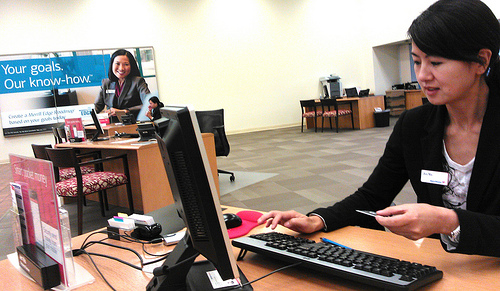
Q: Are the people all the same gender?
A: Yes, all the people are female.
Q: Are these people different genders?
A: No, all the people are female.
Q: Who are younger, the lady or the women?
A: The women are younger than the lady.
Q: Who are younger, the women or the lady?
A: The women are younger than the lady.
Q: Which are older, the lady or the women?
A: The lady are older than the women.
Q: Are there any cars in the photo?
A: No, there are no cars.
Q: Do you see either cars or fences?
A: No, there are no cars or fences.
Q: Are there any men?
A: No, there are no men.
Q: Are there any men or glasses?
A: No, there are no men or glasses.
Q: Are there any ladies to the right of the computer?
A: Yes, there is a lady to the right of the computer.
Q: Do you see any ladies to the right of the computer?
A: Yes, there is a lady to the right of the computer.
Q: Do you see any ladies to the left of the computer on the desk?
A: No, the lady is to the right of the computer.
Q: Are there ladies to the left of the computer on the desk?
A: No, the lady is to the right of the computer.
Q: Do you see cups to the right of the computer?
A: No, there is a lady to the right of the computer.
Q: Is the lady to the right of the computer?
A: Yes, the lady is to the right of the computer.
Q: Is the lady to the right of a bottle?
A: No, the lady is to the right of the computer.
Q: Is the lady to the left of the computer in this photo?
A: No, the lady is to the right of the computer.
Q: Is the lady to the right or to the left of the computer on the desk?
A: The lady is to the right of the computer.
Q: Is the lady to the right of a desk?
A: Yes, the lady is to the right of a desk.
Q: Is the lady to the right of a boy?
A: No, the lady is to the right of a desk.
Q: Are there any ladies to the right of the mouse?
A: Yes, there is a lady to the right of the mouse.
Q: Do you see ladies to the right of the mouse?
A: Yes, there is a lady to the right of the mouse.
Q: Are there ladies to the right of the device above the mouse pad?
A: Yes, there is a lady to the right of the mouse.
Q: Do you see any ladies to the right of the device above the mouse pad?
A: Yes, there is a lady to the right of the mouse.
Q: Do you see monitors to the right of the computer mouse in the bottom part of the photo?
A: No, there is a lady to the right of the computer mouse.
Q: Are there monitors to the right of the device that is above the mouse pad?
A: No, there is a lady to the right of the computer mouse.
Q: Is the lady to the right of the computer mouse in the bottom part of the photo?
A: Yes, the lady is to the right of the computer mouse.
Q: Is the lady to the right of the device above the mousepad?
A: Yes, the lady is to the right of the computer mouse.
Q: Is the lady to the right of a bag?
A: No, the lady is to the right of the computer mouse.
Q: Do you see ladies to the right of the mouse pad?
A: Yes, there is a lady to the right of the mouse pad.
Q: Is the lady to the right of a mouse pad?
A: Yes, the lady is to the right of a mouse pad.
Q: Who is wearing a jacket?
A: The lady is wearing a jacket.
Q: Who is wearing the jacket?
A: The lady is wearing a jacket.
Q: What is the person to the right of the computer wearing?
A: The lady is wearing a jacket.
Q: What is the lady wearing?
A: The lady is wearing a jacket.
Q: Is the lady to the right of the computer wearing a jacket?
A: Yes, the lady is wearing a jacket.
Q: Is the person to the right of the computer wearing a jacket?
A: Yes, the lady is wearing a jacket.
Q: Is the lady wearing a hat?
A: No, the lady is wearing a jacket.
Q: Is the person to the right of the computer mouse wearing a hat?
A: No, the lady is wearing a jacket.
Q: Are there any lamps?
A: No, there are no lamps.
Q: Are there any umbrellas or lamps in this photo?
A: No, there are no lamps or umbrellas.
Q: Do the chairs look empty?
A: Yes, the chairs are empty.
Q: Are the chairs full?
A: No, the chairs are empty.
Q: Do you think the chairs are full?
A: No, the chairs are empty.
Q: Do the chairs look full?
A: No, the chairs are empty.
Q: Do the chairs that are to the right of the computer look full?
A: No, the chairs are empty.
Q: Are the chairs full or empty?
A: The chairs are empty.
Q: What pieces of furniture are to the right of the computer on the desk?
A: The pieces of furniture are chairs.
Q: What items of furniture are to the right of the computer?
A: The pieces of furniture are chairs.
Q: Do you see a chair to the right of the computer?
A: Yes, there are chairs to the right of the computer.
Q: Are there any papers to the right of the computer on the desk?
A: No, there are chairs to the right of the computer.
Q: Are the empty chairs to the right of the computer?
A: Yes, the chairs are to the right of the computer.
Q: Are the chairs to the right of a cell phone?
A: No, the chairs are to the right of the computer.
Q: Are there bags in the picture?
A: No, there are no bags.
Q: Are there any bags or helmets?
A: No, there are no bags or helmets.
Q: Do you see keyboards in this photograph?
A: Yes, there is a keyboard.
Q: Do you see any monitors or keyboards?
A: Yes, there is a keyboard.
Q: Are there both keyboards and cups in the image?
A: No, there is a keyboard but no cups.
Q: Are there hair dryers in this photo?
A: No, there are no hair dryers.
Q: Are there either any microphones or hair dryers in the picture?
A: No, there are no hair dryers or microphones.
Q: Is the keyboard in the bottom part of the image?
A: Yes, the keyboard is in the bottom of the image.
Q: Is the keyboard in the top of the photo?
A: No, the keyboard is in the bottom of the image.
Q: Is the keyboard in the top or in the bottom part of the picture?
A: The keyboard is in the bottom of the image.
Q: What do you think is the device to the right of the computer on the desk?
A: The device is a keyboard.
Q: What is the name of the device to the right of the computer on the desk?
A: The device is a keyboard.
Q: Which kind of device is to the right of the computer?
A: The device is a keyboard.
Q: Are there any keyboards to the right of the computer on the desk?
A: Yes, there is a keyboard to the right of the computer.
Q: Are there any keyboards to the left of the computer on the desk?
A: No, the keyboard is to the right of the computer.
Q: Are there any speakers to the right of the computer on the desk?
A: No, there is a keyboard to the right of the computer.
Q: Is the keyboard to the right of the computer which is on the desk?
A: Yes, the keyboard is to the right of the computer.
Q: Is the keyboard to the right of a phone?
A: No, the keyboard is to the right of the computer.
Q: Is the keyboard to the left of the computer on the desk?
A: No, the keyboard is to the right of the computer.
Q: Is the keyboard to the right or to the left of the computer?
A: The keyboard is to the right of the computer.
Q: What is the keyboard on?
A: The keyboard is on the desk.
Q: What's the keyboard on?
A: The keyboard is on the desk.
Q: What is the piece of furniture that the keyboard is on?
A: The piece of furniture is a desk.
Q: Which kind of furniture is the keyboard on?
A: The keyboard is on the desk.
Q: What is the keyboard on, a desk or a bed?
A: The keyboard is on a desk.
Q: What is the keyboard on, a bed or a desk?
A: The keyboard is on a desk.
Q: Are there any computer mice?
A: Yes, there is a computer mouse.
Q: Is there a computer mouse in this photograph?
A: Yes, there is a computer mouse.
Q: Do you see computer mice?
A: Yes, there is a computer mouse.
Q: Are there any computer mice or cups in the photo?
A: Yes, there is a computer mouse.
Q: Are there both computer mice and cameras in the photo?
A: No, there is a computer mouse but no cameras.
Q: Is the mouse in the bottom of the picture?
A: Yes, the mouse is in the bottom of the image.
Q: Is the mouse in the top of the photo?
A: No, the mouse is in the bottom of the image.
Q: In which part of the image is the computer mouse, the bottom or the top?
A: The computer mouse is in the bottom of the image.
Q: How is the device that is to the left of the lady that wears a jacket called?
A: The device is a computer mouse.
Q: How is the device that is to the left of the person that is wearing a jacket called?
A: The device is a computer mouse.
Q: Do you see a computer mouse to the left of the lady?
A: Yes, there is a computer mouse to the left of the lady.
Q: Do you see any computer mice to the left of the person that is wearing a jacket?
A: Yes, there is a computer mouse to the left of the lady.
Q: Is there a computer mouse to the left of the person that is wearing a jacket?
A: Yes, there is a computer mouse to the left of the lady.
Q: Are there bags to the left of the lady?
A: No, there is a computer mouse to the left of the lady.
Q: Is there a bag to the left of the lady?
A: No, there is a computer mouse to the left of the lady.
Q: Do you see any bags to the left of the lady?
A: No, there is a computer mouse to the left of the lady.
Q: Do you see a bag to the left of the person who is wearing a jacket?
A: No, there is a computer mouse to the left of the lady.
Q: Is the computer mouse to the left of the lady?
A: Yes, the computer mouse is to the left of the lady.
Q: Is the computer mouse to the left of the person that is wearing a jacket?
A: Yes, the computer mouse is to the left of the lady.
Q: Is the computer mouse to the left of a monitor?
A: No, the computer mouse is to the left of the lady.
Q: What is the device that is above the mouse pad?
A: The device is a computer mouse.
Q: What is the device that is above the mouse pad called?
A: The device is a computer mouse.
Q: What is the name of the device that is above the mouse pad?
A: The device is a computer mouse.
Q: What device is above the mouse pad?
A: The device is a computer mouse.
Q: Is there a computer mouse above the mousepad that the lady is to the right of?
A: Yes, there is a computer mouse above the mousepad.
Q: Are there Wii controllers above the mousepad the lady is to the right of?
A: No, there is a computer mouse above the mousepad.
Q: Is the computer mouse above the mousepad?
A: Yes, the computer mouse is above the mousepad.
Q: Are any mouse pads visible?
A: Yes, there is a mouse pad.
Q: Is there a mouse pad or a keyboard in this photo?
A: Yes, there is a mouse pad.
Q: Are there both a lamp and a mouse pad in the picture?
A: No, there is a mouse pad but no lamps.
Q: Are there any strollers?
A: No, there are no strollers.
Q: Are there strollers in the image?
A: No, there are no strollers.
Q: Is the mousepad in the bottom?
A: Yes, the mousepad is in the bottom of the image.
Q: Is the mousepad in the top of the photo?
A: No, the mousepad is in the bottom of the image.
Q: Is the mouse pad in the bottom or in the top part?
A: The mouse pad is in the bottom of the image.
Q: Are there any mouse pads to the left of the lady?
A: Yes, there is a mouse pad to the left of the lady.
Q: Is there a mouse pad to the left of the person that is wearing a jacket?
A: Yes, there is a mouse pad to the left of the lady.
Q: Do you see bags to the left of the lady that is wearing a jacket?
A: No, there is a mouse pad to the left of the lady.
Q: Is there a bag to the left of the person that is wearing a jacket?
A: No, there is a mouse pad to the left of the lady.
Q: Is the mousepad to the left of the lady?
A: Yes, the mousepad is to the left of the lady.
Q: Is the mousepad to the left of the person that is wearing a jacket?
A: Yes, the mousepad is to the left of the lady.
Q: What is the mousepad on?
A: The mousepad is on the desk.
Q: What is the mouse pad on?
A: The mousepad is on the desk.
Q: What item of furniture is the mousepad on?
A: The mousepad is on the desk.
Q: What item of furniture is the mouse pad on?
A: The mousepad is on the desk.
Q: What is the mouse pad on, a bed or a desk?
A: The mouse pad is on a desk.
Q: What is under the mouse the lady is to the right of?
A: The mouse pad is under the mouse.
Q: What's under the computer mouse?
A: The mouse pad is under the mouse.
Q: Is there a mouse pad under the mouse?
A: Yes, there is a mouse pad under the mouse.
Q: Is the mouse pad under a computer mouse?
A: Yes, the mouse pad is under a computer mouse.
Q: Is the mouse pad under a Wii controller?
A: No, the mouse pad is under a computer mouse.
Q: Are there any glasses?
A: No, there are no glasses.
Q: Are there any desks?
A: Yes, there is a desk.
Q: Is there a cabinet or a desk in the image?
A: Yes, there is a desk.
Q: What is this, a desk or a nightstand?
A: This is a desk.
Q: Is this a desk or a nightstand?
A: This is a desk.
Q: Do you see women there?
A: Yes, there are women.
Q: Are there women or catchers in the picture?
A: Yes, there are women.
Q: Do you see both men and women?
A: No, there are women but no men.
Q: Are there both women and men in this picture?
A: No, there are women but no men.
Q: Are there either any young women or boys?
A: Yes, there are young women.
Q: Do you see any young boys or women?
A: Yes, there are young women.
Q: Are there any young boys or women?
A: Yes, there are young women.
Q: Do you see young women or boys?
A: Yes, there are young women.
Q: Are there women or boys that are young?
A: Yes, the women are young.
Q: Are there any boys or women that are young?
A: Yes, the women are young.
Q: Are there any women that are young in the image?
A: Yes, there are young women.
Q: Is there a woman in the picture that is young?
A: Yes, there are women that are young.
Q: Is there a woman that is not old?
A: Yes, there are young women.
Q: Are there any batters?
A: No, there are no batters.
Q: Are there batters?
A: No, there are no batters.